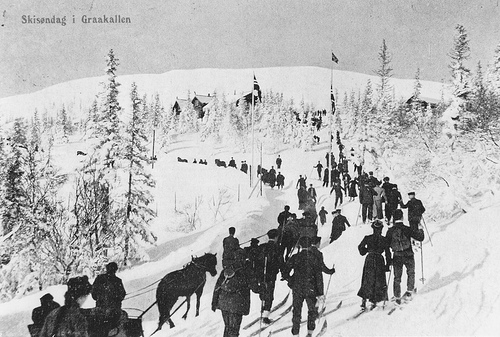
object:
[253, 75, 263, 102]
flag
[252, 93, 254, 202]
pole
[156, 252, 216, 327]
horse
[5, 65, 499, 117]
snow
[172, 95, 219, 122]
house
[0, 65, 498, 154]
hill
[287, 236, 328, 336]
person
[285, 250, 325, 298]
black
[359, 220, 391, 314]
lady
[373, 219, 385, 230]
hat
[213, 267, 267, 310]
coat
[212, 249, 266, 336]
person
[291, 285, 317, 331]
trousers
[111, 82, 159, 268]
tree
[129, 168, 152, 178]
branches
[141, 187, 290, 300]
path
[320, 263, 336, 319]
stick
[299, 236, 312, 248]
hat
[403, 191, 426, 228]
person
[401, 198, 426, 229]
suit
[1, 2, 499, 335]
photo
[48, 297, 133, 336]
sleigh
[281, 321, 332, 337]
skis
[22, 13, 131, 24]
label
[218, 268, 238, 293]
bag